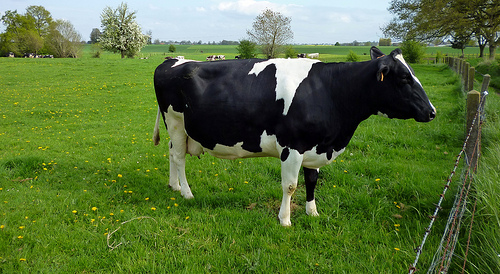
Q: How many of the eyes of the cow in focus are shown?
A: One.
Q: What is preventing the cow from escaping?
A: The fence.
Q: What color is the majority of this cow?
A: Black.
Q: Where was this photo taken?
A: A cow farm.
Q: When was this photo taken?
A: Day time.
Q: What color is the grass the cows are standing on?
A: Green.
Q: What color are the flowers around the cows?
A: Yellow.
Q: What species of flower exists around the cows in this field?
A: Dandelion.